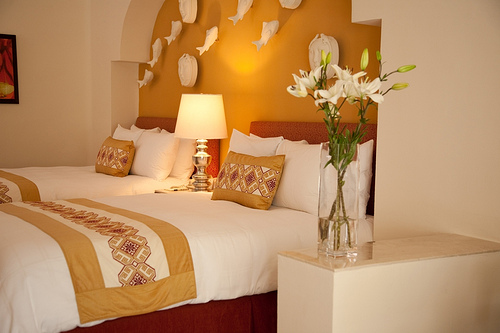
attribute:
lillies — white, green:
[293, 66, 389, 108]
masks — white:
[169, 0, 212, 95]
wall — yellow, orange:
[130, 17, 322, 87]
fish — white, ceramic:
[191, 25, 222, 56]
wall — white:
[7, 10, 91, 174]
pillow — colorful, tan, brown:
[214, 146, 284, 212]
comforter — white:
[13, 192, 302, 291]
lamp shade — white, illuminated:
[169, 93, 236, 141]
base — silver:
[185, 140, 217, 192]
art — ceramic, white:
[193, 23, 287, 52]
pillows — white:
[110, 122, 204, 179]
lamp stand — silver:
[191, 152, 214, 190]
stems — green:
[324, 108, 355, 219]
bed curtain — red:
[178, 302, 272, 333]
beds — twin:
[12, 156, 316, 306]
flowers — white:
[305, 55, 386, 176]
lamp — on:
[163, 91, 240, 197]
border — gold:
[41, 199, 187, 314]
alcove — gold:
[205, 63, 334, 122]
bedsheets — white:
[171, 193, 278, 295]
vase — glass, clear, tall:
[319, 142, 363, 262]